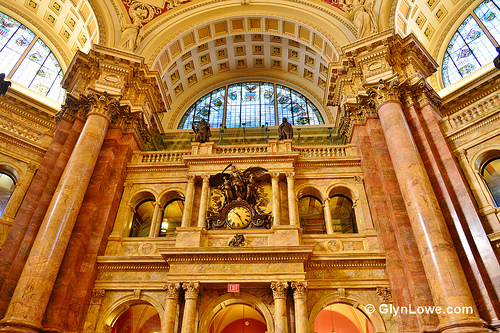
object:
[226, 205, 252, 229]
clock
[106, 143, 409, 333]
wall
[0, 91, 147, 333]
pillar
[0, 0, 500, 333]
building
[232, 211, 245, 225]
arms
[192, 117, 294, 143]
statue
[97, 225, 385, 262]
balcony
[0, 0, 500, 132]
roof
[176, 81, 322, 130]
window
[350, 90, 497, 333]
column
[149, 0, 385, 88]
yellow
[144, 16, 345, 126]
ceiling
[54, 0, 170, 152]
molding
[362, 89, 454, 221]
marble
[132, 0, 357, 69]
top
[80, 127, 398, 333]
middle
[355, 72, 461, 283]
right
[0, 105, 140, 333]
left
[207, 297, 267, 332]
doorway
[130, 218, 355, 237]
rail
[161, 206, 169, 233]
light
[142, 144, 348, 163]
railing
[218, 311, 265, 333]
hallway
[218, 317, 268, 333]
entrance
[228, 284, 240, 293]
exit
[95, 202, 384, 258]
floor